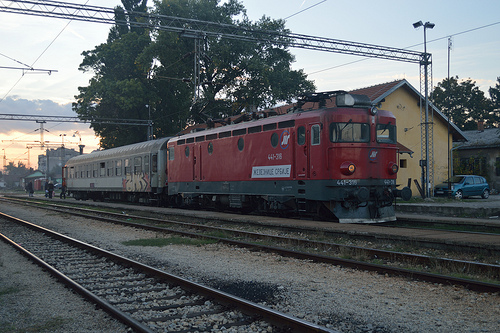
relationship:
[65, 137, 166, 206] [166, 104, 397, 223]
passenger car behind train engine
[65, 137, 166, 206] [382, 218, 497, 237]
passenger car on tracks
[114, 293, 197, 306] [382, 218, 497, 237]
gravel between tracks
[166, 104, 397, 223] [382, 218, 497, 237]
train engine on tracks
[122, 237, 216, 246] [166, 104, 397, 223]
grass near train engine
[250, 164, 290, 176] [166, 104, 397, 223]
writting on train engine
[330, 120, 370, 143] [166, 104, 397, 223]
window on train engine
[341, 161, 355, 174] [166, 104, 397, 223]
light on train engine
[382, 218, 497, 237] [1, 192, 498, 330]
tracks on ground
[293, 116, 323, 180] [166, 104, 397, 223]
door on train engine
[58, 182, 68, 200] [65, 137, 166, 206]
person by passenger car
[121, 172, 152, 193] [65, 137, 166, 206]
graffiti on passenger car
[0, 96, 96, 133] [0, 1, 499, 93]
cloud in sky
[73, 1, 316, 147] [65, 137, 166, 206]
tree behind passenger car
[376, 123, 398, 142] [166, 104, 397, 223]
window on train engine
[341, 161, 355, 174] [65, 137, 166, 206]
light on passenger car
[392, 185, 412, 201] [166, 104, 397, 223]
safety ram on train engine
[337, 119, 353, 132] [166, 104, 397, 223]
windsheild wiper on train engine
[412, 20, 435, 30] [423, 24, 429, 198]
lights on pole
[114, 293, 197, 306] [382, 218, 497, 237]
gravel on tracks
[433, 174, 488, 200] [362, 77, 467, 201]
car beside building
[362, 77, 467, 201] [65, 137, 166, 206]
building beside passenger car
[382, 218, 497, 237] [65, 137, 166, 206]
tracks below passenger car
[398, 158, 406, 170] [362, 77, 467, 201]
window on building